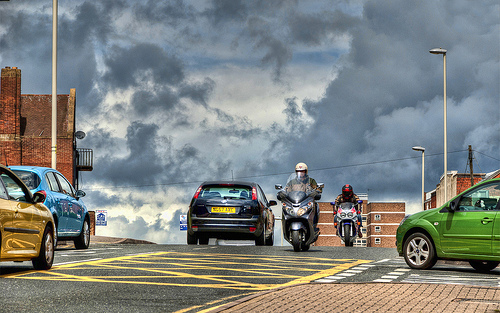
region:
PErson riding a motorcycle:
[277, 151, 325, 273]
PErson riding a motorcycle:
[332, 180, 382, 247]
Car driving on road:
[168, 145, 289, 273]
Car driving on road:
[398, 136, 495, 273]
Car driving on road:
[9, 151, 109, 255]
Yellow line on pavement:
[18, 237, 337, 311]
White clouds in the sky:
[405, 4, 470, 74]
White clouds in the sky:
[348, 9, 399, 87]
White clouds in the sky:
[304, 8, 394, 116]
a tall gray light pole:
[427, 49, 459, 198]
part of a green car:
[390, 177, 498, 275]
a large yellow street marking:
[0, 238, 370, 293]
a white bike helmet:
[296, 162, 310, 170]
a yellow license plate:
[208, 204, 237, 215]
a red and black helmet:
[340, 183, 354, 194]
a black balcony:
[74, 146, 96, 172]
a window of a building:
[374, 212, 382, 220]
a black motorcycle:
[269, 179, 325, 246]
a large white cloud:
[310, 0, 495, 190]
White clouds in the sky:
[15, 10, 71, 35]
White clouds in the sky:
[80, 8, 152, 56]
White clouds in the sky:
[150, 20, 230, 70]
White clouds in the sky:
[267, 28, 365, 97]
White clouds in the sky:
[377, 50, 464, 101]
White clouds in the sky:
[134, 77, 260, 149]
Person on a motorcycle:
[328, 174, 367, 264]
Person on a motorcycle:
[270, 154, 323, 271]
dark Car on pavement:
[185, 156, 277, 260]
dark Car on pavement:
[387, 159, 498, 269]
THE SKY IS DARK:
[119, 83, 420, 168]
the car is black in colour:
[166, 168, 262, 237]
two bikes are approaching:
[272, 148, 367, 265]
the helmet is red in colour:
[331, 168, 357, 195]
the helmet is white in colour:
[293, 155, 308, 171]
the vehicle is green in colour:
[396, 178, 496, 272]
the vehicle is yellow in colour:
[0, 205, 52, 254]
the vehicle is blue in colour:
[33, 169, 100, 222]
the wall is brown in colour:
[12, 102, 79, 156]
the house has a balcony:
[75, 120, 107, 167]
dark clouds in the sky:
[128, 52, 221, 113]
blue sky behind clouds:
[200, 48, 277, 82]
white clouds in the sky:
[208, 50, 273, 115]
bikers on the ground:
[240, 140, 385, 268]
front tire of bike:
[269, 218, 314, 268]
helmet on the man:
[271, 143, 322, 194]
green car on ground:
[384, 166, 497, 253]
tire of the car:
[381, 228, 443, 284]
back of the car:
[188, 173, 264, 243]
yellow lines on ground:
[136, 244, 198, 294]